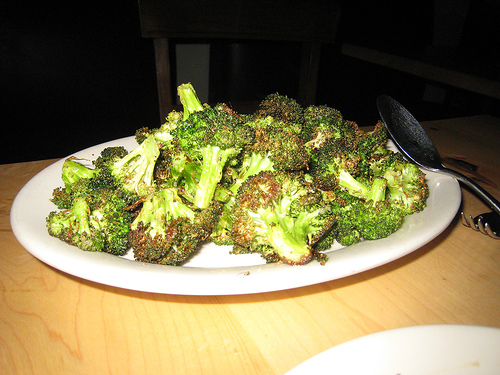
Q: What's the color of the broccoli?
A: Green.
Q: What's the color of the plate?
A: White.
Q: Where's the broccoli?
A: Plate.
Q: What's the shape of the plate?
A: Round.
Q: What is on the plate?
A: Broccoli.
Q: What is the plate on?
A: A table.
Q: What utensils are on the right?
A: A spoon and a fork.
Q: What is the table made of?
A: Wood.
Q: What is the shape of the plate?
A: Round.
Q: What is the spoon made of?
A: Metal.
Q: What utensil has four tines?
A: The fork.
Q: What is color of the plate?
A: White.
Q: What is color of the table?
A: Tan.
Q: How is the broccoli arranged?
A: Piled.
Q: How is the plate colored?
A: White.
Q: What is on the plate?
A: Broccoli.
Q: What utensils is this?
A: Spoon and fork.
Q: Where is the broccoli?
A: White plate.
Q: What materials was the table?
A: Wood.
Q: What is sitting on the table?
A: The white plate.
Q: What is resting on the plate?
A: The spoon.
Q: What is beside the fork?
A: The spoon.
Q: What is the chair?
A: Behind the plate of broccoli.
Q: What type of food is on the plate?
A: Vegetable.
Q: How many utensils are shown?
A: Two.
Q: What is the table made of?
A: Wood.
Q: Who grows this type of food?
A: Farmers.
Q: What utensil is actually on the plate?
A: Spoon.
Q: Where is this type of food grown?
A: Farm.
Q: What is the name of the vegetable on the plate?
A: Broccoli.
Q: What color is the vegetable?
A: Green.